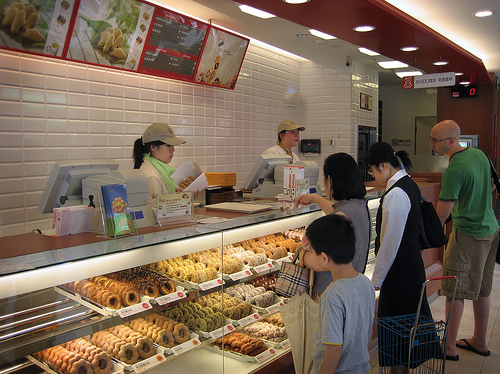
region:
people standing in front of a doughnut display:
[306, 120, 498, 371]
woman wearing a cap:
[142, 121, 186, 148]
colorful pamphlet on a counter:
[100, 183, 136, 238]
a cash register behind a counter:
[36, 161, 156, 228]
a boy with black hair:
[306, 213, 359, 273]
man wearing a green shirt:
[438, 150, 495, 236]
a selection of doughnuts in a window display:
[29, 225, 304, 370]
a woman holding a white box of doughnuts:
[168, 158, 208, 199]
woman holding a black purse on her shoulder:
[412, 183, 447, 252]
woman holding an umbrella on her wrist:
[281, 250, 323, 372]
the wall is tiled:
[19, 74, 129, 139]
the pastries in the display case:
[77, 247, 262, 367]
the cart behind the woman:
[370, 255, 472, 365]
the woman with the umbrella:
[278, 230, 327, 372]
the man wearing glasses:
[418, 110, 498, 290]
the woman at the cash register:
[247, 120, 305, 160]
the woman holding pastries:
[117, 110, 228, 198]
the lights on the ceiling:
[344, 17, 399, 37]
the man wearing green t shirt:
[437, 148, 491, 206]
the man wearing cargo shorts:
[440, 223, 499, 293]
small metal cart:
[377, 274, 460, 372]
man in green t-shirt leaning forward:
[426, 117, 498, 361]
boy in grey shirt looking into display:
[303, 210, 378, 372]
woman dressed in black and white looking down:
[365, 138, 437, 372]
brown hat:
[138, 120, 185, 149]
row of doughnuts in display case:
[183, 264, 215, 285]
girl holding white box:
[126, 119, 208, 209]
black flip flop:
[454, 333, 490, 358]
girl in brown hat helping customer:
[259, 118, 309, 161]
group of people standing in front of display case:
[271, 117, 498, 371]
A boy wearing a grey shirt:
[297, 207, 388, 372]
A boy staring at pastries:
[290, 205, 376, 370]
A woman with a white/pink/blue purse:
[272, 151, 377, 371]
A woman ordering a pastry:
[270, 137, 390, 367]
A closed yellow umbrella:
[271, 245, 331, 370]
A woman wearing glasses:
[360, 130, 455, 370]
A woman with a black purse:
[350, 125, 455, 370]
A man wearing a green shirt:
[415, 110, 495, 360]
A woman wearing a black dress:
[355, 135, 455, 370]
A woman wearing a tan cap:
[125, 108, 190, 209]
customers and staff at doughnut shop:
[12, 8, 483, 355]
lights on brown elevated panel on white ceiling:
[200, 0, 495, 100]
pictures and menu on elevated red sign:
[5, 5, 246, 91]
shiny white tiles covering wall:
[5, 12, 375, 229]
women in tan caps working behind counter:
[116, 115, 306, 191]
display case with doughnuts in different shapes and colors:
[2, 221, 297, 371]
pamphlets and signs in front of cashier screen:
[35, 155, 186, 230]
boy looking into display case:
[300, 200, 370, 370]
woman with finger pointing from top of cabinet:
[290, 146, 367, 216]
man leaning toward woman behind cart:
[370, 101, 495, 366]